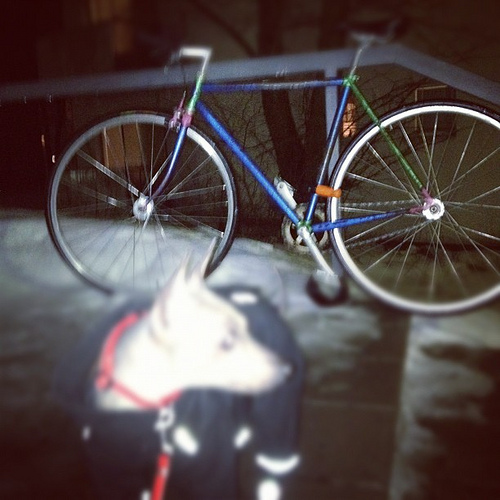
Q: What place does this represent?
A: It represents the porch.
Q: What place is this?
A: It is a porch.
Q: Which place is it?
A: It is a porch.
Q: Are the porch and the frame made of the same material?
A: No, the porch is made of concrete and the frame is made of metal.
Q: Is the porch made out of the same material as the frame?
A: No, the porch is made of concrete and the frame is made of metal.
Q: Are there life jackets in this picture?
A: No, there are no life jackets.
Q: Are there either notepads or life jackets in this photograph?
A: No, there are no life jackets or notepads.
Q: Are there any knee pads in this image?
A: No, there are no knee pads.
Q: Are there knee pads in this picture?
A: No, there are no knee pads.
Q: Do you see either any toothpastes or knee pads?
A: No, there are no knee pads or toothpastes.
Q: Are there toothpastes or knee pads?
A: No, there are no knee pads or toothpastes.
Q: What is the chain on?
A: The chain is on the bicycle.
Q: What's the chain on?
A: The chain is on the bicycle.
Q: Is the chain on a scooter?
A: No, the chain is on the bicycle.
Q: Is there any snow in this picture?
A: Yes, there is snow.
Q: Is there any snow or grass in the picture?
A: Yes, there is snow.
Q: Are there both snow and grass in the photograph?
A: No, there is snow but no grass.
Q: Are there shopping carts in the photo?
A: No, there are no shopping carts.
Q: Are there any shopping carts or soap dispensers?
A: No, there are no shopping carts or soap dispensers.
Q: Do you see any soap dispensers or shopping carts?
A: No, there are no shopping carts or soap dispensers.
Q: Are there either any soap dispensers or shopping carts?
A: No, there are no shopping carts or soap dispensers.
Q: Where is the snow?
A: The snow is on the porch.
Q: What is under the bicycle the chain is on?
A: The snow is under the bicycle.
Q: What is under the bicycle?
A: The snow is under the bicycle.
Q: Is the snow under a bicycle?
A: Yes, the snow is under a bicycle.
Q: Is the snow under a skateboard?
A: No, the snow is under a bicycle.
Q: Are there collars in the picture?
A: Yes, there is a collar.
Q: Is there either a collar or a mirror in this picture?
A: Yes, there is a collar.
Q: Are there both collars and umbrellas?
A: No, there is a collar but no umbrellas.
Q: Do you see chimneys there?
A: No, there are no chimneys.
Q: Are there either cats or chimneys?
A: No, there are no chimneys or cats.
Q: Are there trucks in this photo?
A: No, there are no trucks.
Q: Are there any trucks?
A: No, there are no trucks.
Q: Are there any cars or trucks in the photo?
A: No, there are no trucks or cars.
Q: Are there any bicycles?
A: Yes, there is a bicycle.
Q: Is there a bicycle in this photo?
A: Yes, there is a bicycle.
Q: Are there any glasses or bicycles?
A: Yes, there is a bicycle.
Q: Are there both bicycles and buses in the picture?
A: No, there is a bicycle but no buses.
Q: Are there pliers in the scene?
A: No, there are no pliers.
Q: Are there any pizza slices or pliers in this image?
A: No, there are no pliers or pizza slices.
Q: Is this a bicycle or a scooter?
A: This is a bicycle.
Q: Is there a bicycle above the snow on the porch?
A: Yes, there is a bicycle above the snow.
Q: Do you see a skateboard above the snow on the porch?
A: No, there is a bicycle above the snow.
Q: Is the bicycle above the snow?
A: Yes, the bicycle is above the snow.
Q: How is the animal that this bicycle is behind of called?
A: The animal is a dog.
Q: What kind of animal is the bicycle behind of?
A: The bicycle is behind the dog.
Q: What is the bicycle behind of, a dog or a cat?
A: The bicycle is behind a dog.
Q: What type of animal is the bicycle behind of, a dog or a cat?
A: The bicycle is behind a dog.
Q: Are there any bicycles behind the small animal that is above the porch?
A: Yes, there is a bicycle behind the dog.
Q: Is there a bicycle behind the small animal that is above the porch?
A: Yes, there is a bicycle behind the dog.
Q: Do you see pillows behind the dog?
A: No, there is a bicycle behind the dog.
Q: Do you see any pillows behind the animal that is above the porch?
A: No, there is a bicycle behind the dog.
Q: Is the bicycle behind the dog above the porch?
A: Yes, the bicycle is behind the dog.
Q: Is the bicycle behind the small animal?
A: Yes, the bicycle is behind the dog.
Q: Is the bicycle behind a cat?
A: No, the bicycle is behind the dog.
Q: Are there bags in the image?
A: No, there are no bags.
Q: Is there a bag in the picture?
A: No, there are no bags.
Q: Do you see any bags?
A: No, there are no bags.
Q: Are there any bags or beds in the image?
A: No, there are no bags or beds.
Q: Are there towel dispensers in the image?
A: No, there are no towel dispensers.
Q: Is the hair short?
A: Yes, the hair is short.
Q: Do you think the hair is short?
A: Yes, the hair is short.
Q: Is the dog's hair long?
A: No, the hair is short.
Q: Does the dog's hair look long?
A: No, the hair is short.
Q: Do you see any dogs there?
A: Yes, there is a dog.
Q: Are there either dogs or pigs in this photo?
A: Yes, there is a dog.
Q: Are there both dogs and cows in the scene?
A: No, there is a dog but no cows.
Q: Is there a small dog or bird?
A: Yes, there is a small dog.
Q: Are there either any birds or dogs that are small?
A: Yes, the dog is small.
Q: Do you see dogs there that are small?
A: Yes, there is a small dog.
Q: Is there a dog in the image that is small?
A: Yes, there is a dog that is small.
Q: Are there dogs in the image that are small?
A: Yes, there is a dog that is small.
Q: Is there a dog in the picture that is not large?
A: Yes, there is a small dog.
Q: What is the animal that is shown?
A: The animal is a dog.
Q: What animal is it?
A: The animal is a dog.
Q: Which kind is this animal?
A: This is a dog.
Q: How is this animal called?
A: This is a dog.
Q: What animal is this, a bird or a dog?
A: This is a dog.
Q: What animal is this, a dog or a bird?
A: This is a dog.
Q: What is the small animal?
A: The animal is a dog.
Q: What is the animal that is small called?
A: The animal is a dog.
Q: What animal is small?
A: The animal is a dog.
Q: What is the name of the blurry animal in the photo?
A: The animal is a dog.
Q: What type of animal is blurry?
A: The animal is a dog.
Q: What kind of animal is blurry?
A: The animal is a dog.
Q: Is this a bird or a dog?
A: This is a dog.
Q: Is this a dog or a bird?
A: This is a dog.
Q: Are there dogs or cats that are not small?
A: No, there is a dog but it is small.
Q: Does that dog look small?
A: Yes, the dog is small.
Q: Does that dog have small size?
A: Yes, the dog is small.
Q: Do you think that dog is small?
A: Yes, the dog is small.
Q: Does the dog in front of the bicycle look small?
A: Yes, the dog is small.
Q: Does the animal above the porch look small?
A: Yes, the dog is small.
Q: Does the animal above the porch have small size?
A: Yes, the dog is small.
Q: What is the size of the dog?
A: The dog is small.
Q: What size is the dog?
A: The dog is small.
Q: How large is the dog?
A: The dog is small.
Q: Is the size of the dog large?
A: No, the dog is small.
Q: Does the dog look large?
A: No, the dog is small.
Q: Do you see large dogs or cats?
A: No, there is a dog but it is small.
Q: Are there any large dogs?
A: No, there is a dog but it is small.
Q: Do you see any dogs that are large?
A: No, there is a dog but it is small.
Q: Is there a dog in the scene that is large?
A: No, there is a dog but it is small.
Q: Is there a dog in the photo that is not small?
A: No, there is a dog but it is small.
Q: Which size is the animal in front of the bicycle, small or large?
A: The dog is small.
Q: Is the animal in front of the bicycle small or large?
A: The dog is small.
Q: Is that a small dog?
A: Yes, that is a small dog.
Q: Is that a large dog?
A: No, that is a small dog.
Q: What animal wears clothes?
A: The dog wears clothes.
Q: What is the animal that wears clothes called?
A: The animal is a dog.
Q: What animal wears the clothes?
A: The animal is a dog.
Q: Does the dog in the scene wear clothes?
A: Yes, the dog wears clothes.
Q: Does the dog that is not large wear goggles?
A: No, the dog wears clothes.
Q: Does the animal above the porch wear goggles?
A: No, the dog wears clothes.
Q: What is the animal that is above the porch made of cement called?
A: The animal is a dog.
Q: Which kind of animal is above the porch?
A: The animal is a dog.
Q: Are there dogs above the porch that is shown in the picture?
A: Yes, there is a dog above the porch.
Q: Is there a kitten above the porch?
A: No, there is a dog above the porch.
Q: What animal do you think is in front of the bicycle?
A: The dog is in front of the bicycle.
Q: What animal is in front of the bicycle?
A: The dog is in front of the bicycle.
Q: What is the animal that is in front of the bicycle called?
A: The animal is a dog.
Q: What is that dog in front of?
A: The dog is in front of the bicycle.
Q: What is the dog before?
A: The dog is in front of the bicycle.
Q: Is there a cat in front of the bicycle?
A: No, there is a dog in front of the bicycle.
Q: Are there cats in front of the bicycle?
A: No, there is a dog in front of the bicycle.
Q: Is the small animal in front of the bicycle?
A: Yes, the dog is in front of the bicycle.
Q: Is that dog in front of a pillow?
A: No, the dog is in front of the bicycle.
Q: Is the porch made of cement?
A: Yes, the porch is made of cement.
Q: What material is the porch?
A: The porch is made of concrete.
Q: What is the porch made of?
A: The porch is made of concrete.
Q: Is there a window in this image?
A: Yes, there is a window.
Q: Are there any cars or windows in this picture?
A: Yes, there is a window.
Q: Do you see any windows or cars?
A: Yes, there is a window.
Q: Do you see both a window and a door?
A: No, there is a window but no doors.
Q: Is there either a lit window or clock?
A: Yes, there is a lit window.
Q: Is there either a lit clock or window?
A: Yes, there is a lit window.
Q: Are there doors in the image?
A: No, there are no doors.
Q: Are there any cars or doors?
A: No, there are no doors or cars.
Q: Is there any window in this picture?
A: Yes, there is a window.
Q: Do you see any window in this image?
A: Yes, there is a window.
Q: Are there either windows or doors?
A: Yes, there is a window.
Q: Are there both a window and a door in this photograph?
A: No, there is a window but no doors.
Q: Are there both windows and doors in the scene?
A: No, there is a window but no doors.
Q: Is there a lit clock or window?
A: Yes, there is a lit window.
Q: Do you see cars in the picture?
A: No, there are no cars.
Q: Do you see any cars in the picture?
A: No, there are no cars.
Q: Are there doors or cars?
A: No, there are no cars or doors.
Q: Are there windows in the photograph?
A: Yes, there is a window.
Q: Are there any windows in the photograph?
A: Yes, there is a window.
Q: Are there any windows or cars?
A: Yes, there is a window.